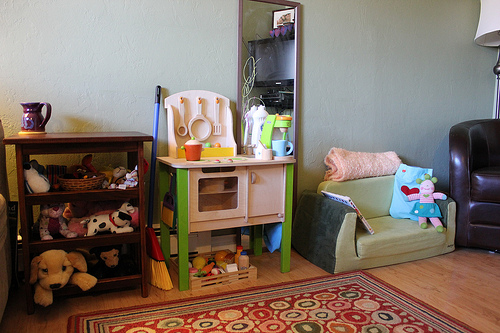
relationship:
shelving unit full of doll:
[4, 130, 154, 313] [404, 172, 448, 232]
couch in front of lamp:
[448, 115, 499, 257] [471, 0, 499, 120]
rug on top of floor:
[66, 268, 483, 331] [1, 245, 499, 331]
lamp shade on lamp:
[471, 0, 499, 48] [471, 0, 499, 120]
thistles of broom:
[143, 253, 173, 291] [144, 84, 173, 290]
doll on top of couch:
[404, 172, 448, 232] [292, 172, 456, 275]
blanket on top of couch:
[321, 145, 401, 180] [292, 172, 456, 275]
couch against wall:
[448, 115, 499, 257] [1, 1, 499, 238]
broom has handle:
[144, 84, 173, 290] [145, 83, 162, 229]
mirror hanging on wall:
[235, 1, 304, 255] [1, 1, 499, 238]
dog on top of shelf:
[26, 248, 97, 310] [30, 274, 140, 299]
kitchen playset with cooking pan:
[155, 89, 298, 290] [188, 96, 211, 143]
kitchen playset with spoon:
[155, 89, 298, 290] [176, 93, 187, 139]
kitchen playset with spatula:
[155, 89, 298, 290] [211, 94, 222, 139]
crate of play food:
[173, 247, 256, 292] [185, 244, 250, 279]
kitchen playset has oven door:
[155, 89, 298, 290] [188, 167, 247, 226]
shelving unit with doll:
[4, 130, 154, 313] [404, 172, 448, 232]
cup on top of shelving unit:
[16, 100, 52, 135] [4, 130, 154, 313]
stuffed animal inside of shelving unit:
[81, 201, 137, 236] [4, 130, 154, 313]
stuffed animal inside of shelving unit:
[32, 198, 76, 240] [4, 130, 154, 313]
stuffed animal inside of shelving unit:
[87, 241, 135, 278] [4, 130, 154, 313]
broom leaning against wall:
[144, 84, 173, 290] [1, 1, 499, 238]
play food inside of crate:
[185, 244, 250, 279] [173, 247, 256, 292]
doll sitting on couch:
[404, 172, 448, 232] [292, 172, 456, 275]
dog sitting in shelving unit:
[26, 248, 97, 310] [4, 130, 154, 313]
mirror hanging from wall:
[235, 1, 304, 255] [1, 1, 499, 238]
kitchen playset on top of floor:
[155, 89, 298, 290] [1, 245, 499, 331]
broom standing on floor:
[144, 84, 173, 290] [1, 245, 499, 331]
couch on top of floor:
[292, 172, 456, 275] [1, 245, 499, 331]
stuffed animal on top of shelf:
[32, 198, 76, 240] [27, 231, 140, 252]